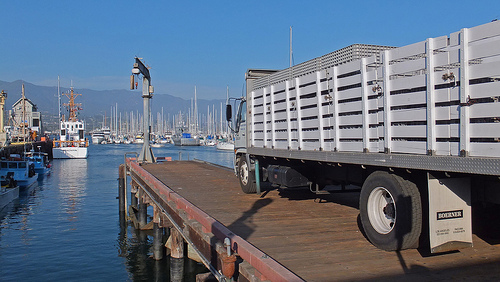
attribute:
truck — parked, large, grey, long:
[187, 18, 500, 245]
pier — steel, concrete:
[113, 141, 499, 282]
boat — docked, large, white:
[44, 73, 96, 161]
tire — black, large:
[338, 159, 440, 253]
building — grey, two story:
[5, 78, 48, 162]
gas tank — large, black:
[258, 155, 326, 195]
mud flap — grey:
[419, 163, 480, 262]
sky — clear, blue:
[5, 0, 499, 98]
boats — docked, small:
[0, 141, 56, 217]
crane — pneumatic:
[122, 51, 163, 174]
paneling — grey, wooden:
[248, 21, 500, 158]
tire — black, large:
[229, 150, 262, 202]